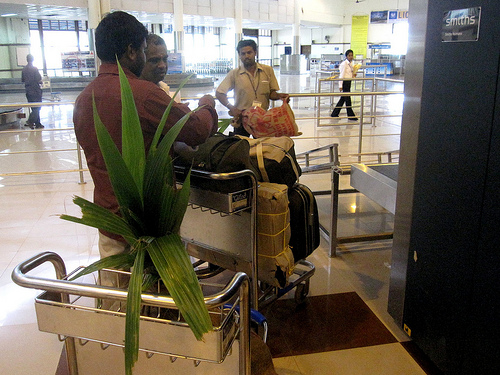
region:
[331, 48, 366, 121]
Person walking behind metal railing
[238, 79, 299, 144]
Man holding a red and white sack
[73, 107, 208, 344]
Green house plant on back of cart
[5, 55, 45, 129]
Person standing near baggage carousel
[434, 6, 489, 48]
Black and white sign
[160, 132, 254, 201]
Dark green duffel back on cart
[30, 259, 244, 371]
Metal basket in cart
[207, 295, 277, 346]
Blue and silver metal handle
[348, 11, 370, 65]
Yellow banner hanging from ceiling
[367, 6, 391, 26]
Telecision screen on wall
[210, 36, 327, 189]
man is carrying a sack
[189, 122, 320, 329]
bags on the cart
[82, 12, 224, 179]
two men are talking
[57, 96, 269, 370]
a plant on the cart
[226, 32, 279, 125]
man is wearing a lanyard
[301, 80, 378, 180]
the railings are silver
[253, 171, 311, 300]
the box has rope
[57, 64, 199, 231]
the shirt is maroon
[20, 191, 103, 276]
the floor is tiled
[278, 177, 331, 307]
the suitcase is black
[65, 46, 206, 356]
green plant in metal roller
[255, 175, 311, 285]
suitcases on metal roller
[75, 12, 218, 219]
man in maroon color shirt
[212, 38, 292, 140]
man in uniform wearing a badge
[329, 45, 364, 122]
woman in black pants and white blouse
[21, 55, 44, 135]
man standing in the background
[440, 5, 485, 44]
small sign on the wall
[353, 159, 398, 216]
beginning of a conveyer belt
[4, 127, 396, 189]
metal divider gate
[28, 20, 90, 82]
bright glass window in the background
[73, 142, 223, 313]
Green plant in the cart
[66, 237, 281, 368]
Silver luggage cart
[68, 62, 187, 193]
Man in a brown shirt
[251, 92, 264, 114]
Man wearing a Identification badge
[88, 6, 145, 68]
Man with black hair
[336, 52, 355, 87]
Person wearing a white shirt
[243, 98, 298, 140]
Man holding a bag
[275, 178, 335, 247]
Black suitcase on a luggage cart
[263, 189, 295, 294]
Brown package on a luggage cart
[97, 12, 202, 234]
Two men standing together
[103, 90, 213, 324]
a green plant in a basket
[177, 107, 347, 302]
a cart with luggage on it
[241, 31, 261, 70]
a man with black hair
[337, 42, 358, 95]
a man wearing a white shirt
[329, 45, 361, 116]
a man wearing black pants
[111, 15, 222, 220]
two men standing next to a luggage cart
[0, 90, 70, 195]
a metal railing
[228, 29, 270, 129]
a man with a tag around his neck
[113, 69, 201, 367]
a green plant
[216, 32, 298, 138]
a man holding a bag